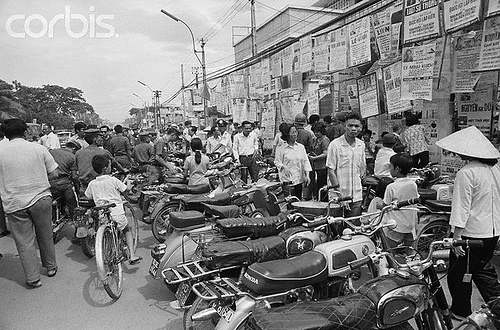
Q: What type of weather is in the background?
A: It is cloudy.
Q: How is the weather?
A: It is cloudy.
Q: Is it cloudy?
A: Yes, it is cloudy.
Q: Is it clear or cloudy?
A: It is cloudy.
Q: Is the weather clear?
A: No, it is cloudy.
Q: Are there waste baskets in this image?
A: No, there are no waste baskets.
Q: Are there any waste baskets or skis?
A: No, there are no waste baskets or skis.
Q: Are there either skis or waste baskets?
A: No, there are no waste baskets or skis.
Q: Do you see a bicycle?
A: Yes, there is a bicycle.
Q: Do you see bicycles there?
A: Yes, there is a bicycle.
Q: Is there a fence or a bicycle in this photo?
A: Yes, there is a bicycle.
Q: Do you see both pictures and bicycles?
A: No, there is a bicycle but no pictures.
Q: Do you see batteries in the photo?
A: No, there are no batteries.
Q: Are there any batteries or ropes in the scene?
A: No, there are no batteries or ropes.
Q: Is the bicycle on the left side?
A: Yes, the bicycle is on the left of the image.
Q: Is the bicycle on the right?
A: No, the bicycle is on the left of the image.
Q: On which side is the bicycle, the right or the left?
A: The bicycle is on the left of the image.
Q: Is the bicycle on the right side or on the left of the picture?
A: The bicycle is on the left of the image.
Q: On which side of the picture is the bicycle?
A: The bicycle is on the left of the image.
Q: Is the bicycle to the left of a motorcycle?
A: Yes, the bicycle is to the left of a motorcycle.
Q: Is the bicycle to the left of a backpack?
A: No, the bicycle is to the left of a motorcycle.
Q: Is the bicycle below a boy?
A: Yes, the bicycle is below a boy.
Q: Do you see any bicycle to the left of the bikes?
A: Yes, there is a bicycle to the left of the bikes.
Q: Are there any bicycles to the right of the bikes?
A: No, the bicycle is to the left of the bikes.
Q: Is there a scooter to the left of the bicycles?
A: No, there is a bicycle to the left of the bicycles.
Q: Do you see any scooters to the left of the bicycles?
A: No, there is a bicycle to the left of the bicycles.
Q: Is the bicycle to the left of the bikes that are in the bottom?
A: Yes, the bicycle is to the left of the bikes.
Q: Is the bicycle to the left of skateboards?
A: No, the bicycle is to the left of the bikes.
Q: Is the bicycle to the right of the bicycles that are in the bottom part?
A: No, the bicycle is to the left of the bicycles.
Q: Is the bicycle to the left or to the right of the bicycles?
A: The bicycle is to the left of the bicycles.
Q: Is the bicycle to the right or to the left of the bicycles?
A: The bicycle is to the left of the bicycles.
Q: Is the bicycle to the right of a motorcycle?
A: No, the bicycle is to the left of a motorcycle.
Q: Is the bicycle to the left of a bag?
A: No, the bicycle is to the left of a motorcycle.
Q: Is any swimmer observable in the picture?
A: No, there are no swimmers.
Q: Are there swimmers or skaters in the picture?
A: No, there are no swimmers or skaters.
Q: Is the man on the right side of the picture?
A: Yes, the man is on the right of the image.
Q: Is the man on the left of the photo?
A: No, the man is on the right of the image.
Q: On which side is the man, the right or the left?
A: The man is on the right of the image.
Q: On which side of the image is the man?
A: The man is on the right of the image.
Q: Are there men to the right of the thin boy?
A: Yes, there is a man to the right of the boy.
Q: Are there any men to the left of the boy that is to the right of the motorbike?
A: No, the man is to the right of the boy.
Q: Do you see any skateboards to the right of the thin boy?
A: No, there is a man to the right of the boy.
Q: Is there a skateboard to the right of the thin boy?
A: No, there is a man to the right of the boy.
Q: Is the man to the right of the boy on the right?
A: Yes, the man is to the right of the boy.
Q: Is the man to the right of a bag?
A: No, the man is to the right of the boy.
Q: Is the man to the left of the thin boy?
A: No, the man is to the right of the boy.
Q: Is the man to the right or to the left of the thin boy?
A: The man is to the right of the boy.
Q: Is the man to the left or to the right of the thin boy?
A: The man is to the right of the boy.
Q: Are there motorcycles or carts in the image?
A: Yes, there is a motorcycle.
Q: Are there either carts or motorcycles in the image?
A: Yes, there is a motorcycle.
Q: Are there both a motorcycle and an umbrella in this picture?
A: No, there is a motorcycle but no umbrellas.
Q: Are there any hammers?
A: No, there are no hammers.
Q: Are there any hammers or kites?
A: No, there are no hammers or kites.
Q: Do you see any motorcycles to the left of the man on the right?
A: Yes, there is a motorcycle to the left of the man.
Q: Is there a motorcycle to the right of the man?
A: No, the motorcycle is to the left of the man.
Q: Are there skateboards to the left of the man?
A: No, there is a motorcycle to the left of the man.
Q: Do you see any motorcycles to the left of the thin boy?
A: Yes, there is a motorcycle to the left of the boy.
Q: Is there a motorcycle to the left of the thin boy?
A: Yes, there is a motorcycle to the left of the boy.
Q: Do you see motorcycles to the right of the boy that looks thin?
A: No, the motorcycle is to the left of the boy.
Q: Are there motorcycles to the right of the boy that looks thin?
A: No, the motorcycle is to the left of the boy.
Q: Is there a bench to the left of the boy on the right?
A: No, there is a motorcycle to the left of the boy.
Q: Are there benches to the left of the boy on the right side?
A: No, there is a motorcycle to the left of the boy.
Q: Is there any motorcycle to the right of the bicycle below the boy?
A: Yes, there is a motorcycle to the right of the bicycle.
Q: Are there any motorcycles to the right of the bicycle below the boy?
A: Yes, there is a motorcycle to the right of the bicycle.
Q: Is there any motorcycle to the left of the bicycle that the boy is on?
A: No, the motorcycle is to the right of the bicycle.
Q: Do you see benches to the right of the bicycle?
A: No, there is a motorcycle to the right of the bicycle.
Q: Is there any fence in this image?
A: No, there are no fences.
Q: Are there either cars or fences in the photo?
A: No, there are no fences or cars.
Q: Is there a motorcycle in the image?
A: Yes, there is a motorcycle.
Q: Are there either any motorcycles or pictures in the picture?
A: Yes, there is a motorcycle.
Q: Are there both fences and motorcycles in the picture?
A: No, there is a motorcycle but no fences.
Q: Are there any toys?
A: No, there are no toys.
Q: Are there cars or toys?
A: No, there are no toys or cars.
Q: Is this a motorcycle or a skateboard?
A: This is a motorcycle.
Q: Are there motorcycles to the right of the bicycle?
A: Yes, there is a motorcycle to the right of the bicycle.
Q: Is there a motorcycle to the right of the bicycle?
A: Yes, there is a motorcycle to the right of the bicycle.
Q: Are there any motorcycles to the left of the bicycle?
A: No, the motorcycle is to the right of the bicycle.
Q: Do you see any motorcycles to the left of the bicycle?
A: No, the motorcycle is to the right of the bicycle.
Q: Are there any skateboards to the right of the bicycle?
A: No, there is a motorcycle to the right of the bicycle.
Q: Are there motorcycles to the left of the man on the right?
A: Yes, there is a motorcycle to the left of the man.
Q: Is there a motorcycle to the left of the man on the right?
A: Yes, there is a motorcycle to the left of the man.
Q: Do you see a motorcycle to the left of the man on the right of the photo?
A: Yes, there is a motorcycle to the left of the man.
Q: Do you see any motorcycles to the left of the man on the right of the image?
A: Yes, there is a motorcycle to the left of the man.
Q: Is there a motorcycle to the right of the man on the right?
A: No, the motorcycle is to the left of the man.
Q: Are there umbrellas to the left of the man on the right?
A: No, there is a motorcycle to the left of the man.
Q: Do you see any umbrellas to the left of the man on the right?
A: No, there is a motorcycle to the left of the man.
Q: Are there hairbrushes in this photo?
A: No, there are no hairbrushes.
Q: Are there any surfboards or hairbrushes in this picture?
A: No, there are no hairbrushes or surfboards.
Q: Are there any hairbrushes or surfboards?
A: No, there are no hairbrushes or surfboards.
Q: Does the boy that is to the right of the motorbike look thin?
A: Yes, the boy is thin.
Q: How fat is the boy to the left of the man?
A: The boy is thin.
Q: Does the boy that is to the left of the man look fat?
A: No, the boy is thin.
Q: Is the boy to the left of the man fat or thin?
A: The boy is thin.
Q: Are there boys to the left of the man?
A: Yes, there is a boy to the left of the man.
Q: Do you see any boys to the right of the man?
A: No, the boy is to the left of the man.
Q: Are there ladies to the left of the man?
A: No, there is a boy to the left of the man.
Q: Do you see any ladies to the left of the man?
A: No, there is a boy to the left of the man.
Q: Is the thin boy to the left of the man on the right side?
A: Yes, the boy is to the left of the man.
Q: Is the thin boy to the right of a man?
A: No, the boy is to the left of a man.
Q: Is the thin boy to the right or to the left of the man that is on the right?
A: The boy is to the left of the man.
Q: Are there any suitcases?
A: No, there are no suitcases.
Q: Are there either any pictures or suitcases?
A: No, there are no suitcases or pictures.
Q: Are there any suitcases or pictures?
A: No, there are no suitcases or pictures.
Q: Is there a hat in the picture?
A: Yes, there is a hat.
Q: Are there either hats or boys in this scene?
A: Yes, there is a hat.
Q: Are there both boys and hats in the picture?
A: Yes, there are both a hat and a boy.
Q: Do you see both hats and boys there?
A: Yes, there are both a hat and a boy.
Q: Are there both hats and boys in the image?
A: Yes, there are both a hat and a boy.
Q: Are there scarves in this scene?
A: No, there are no scarves.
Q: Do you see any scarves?
A: No, there are no scarves.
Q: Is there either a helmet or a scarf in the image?
A: No, there are no scarves or helmets.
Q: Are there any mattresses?
A: No, there are no mattresses.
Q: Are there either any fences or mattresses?
A: No, there are no mattresses or fences.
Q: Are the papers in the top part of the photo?
A: Yes, the papers are in the top of the image.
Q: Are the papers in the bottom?
A: No, the papers are in the top of the image.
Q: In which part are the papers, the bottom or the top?
A: The papers are in the top of the image.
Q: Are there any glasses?
A: No, there are no glasses.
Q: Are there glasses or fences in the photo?
A: No, there are no glasses or fences.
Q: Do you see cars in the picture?
A: No, there are no cars.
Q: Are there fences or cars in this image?
A: No, there are no cars or fences.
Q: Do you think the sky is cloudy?
A: Yes, the sky is cloudy.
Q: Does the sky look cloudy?
A: Yes, the sky is cloudy.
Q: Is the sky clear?
A: No, the sky is cloudy.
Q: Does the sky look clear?
A: No, the sky is cloudy.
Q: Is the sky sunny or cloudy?
A: The sky is cloudy.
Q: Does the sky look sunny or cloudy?
A: The sky is cloudy.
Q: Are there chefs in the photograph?
A: No, there are no chefs.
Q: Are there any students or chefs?
A: No, there are no chefs or students.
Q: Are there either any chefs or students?
A: No, there are no chefs or students.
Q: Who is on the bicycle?
A: The boy is on the bicycle.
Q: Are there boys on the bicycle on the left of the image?
A: Yes, there is a boy on the bicycle.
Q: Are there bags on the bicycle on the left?
A: No, there is a boy on the bicycle.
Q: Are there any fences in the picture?
A: No, there are no fences.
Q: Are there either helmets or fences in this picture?
A: No, there are no fences or helmets.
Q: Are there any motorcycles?
A: Yes, there is a motorcycle.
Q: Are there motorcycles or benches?
A: Yes, there is a motorcycle.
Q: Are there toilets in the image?
A: No, there are no toilets.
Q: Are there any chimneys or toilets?
A: No, there are no toilets or chimneys.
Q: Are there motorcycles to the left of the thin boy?
A: Yes, there is a motorcycle to the left of the boy.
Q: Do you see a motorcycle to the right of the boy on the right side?
A: No, the motorcycle is to the left of the boy.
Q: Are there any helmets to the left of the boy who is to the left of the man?
A: No, there is a motorcycle to the left of the boy.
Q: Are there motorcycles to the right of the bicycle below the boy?
A: Yes, there is a motorcycle to the right of the bicycle.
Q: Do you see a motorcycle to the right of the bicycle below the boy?
A: Yes, there is a motorcycle to the right of the bicycle.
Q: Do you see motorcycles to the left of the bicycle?
A: No, the motorcycle is to the right of the bicycle.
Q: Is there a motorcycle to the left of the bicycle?
A: No, the motorcycle is to the right of the bicycle.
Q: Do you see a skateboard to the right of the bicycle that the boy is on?
A: No, there is a motorcycle to the right of the bicycle.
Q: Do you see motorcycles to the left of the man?
A: Yes, there is a motorcycle to the left of the man.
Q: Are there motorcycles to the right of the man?
A: No, the motorcycle is to the left of the man.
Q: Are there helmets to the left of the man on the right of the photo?
A: No, there is a motorcycle to the left of the man.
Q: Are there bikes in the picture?
A: Yes, there are bikes.